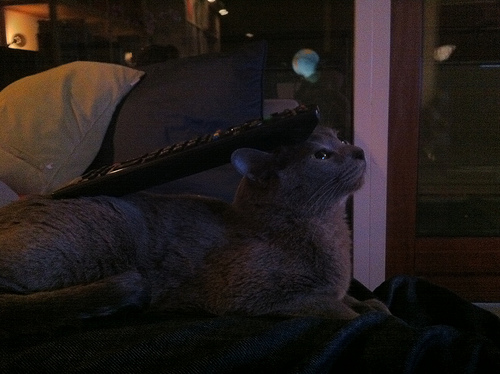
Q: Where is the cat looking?
A: Up at the ceiling.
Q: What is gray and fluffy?
A: The cat.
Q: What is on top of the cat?
A: A remote control.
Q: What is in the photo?
A: A cat.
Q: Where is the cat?
A: In the photo.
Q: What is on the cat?
A: Remote.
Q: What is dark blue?
A: Pillow.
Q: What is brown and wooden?
A: Door.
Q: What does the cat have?
A: Whiskers.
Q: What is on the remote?
A: Buttons.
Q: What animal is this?
A: Cat.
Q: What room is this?
A: Living room.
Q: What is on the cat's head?
A: Remote control.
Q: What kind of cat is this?
A: House cat.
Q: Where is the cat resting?
A: Lap.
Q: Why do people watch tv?
A: Entertainment.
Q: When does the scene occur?
A: Night time.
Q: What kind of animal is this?
A: A cat.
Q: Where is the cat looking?
A: To the right.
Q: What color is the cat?
A: Gray.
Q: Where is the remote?
A: On top of the cat.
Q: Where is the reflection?
A: In the window.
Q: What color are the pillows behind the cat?
A: Tan and black.